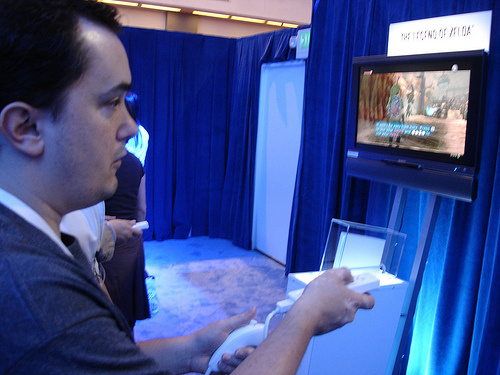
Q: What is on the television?
A: A game.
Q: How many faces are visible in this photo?
A: One.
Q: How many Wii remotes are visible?
A: Two.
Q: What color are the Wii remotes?
A: White.